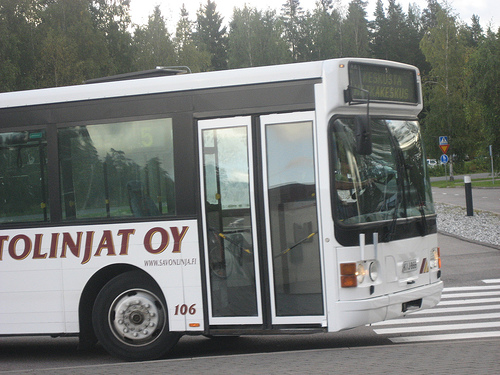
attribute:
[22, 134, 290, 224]
windows — glass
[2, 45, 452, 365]
bus — white, parked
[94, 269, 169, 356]
wheel — turning away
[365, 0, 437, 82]
tree — tall, deciduous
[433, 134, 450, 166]
sign — red, blue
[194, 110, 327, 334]
door — double, closed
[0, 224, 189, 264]
letters — red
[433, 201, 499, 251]
median — gravel covered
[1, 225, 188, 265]
name — bus company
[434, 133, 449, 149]
sign — blue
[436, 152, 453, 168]
sign — blue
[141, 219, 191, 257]
oy — red